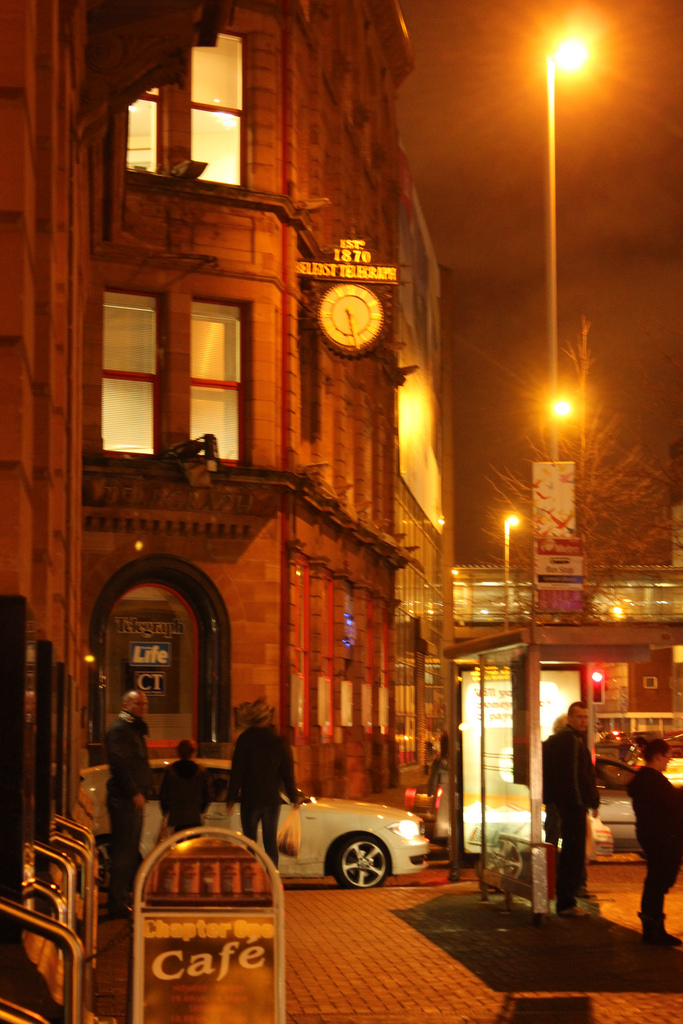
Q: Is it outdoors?
A: Yes, it is outdoors.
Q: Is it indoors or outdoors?
A: It is outdoors.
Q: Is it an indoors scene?
A: No, it is outdoors.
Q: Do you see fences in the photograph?
A: No, there are no fences.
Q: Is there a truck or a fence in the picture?
A: No, there are no fences or trucks.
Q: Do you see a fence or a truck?
A: No, there are no fences or trucks.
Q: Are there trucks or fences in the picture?
A: No, there are no fences or trucks.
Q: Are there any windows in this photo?
A: Yes, there is a window.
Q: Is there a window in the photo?
A: Yes, there is a window.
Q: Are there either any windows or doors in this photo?
A: Yes, there is a window.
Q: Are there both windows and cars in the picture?
A: Yes, there are both a window and a car.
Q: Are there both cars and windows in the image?
A: Yes, there are both a window and a car.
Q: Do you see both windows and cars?
A: Yes, there are both a window and a car.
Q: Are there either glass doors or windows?
A: Yes, there is a glass window.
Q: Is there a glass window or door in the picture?
A: Yes, there is a glass window.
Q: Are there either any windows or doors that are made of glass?
A: Yes, the window is made of glass.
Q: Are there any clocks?
A: Yes, there is a clock.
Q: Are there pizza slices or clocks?
A: Yes, there is a clock.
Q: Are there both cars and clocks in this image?
A: Yes, there are both a clock and a car.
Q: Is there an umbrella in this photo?
A: No, there are no umbrellas.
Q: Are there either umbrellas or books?
A: No, there are no umbrellas or books.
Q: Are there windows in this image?
A: Yes, there is a window.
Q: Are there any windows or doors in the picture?
A: Yes, there is a window.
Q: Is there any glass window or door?
A: Yes, there is a glass window.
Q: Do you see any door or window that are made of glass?
A: Yes, the window is made of glass.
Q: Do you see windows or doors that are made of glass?
A: Yes, the window is made of glass.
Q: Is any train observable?
A: No, there are no trains.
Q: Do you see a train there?
A: No, there are no trains.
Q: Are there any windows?
A: Yes, there is a window.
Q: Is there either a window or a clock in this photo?
A: Yes, there is a window.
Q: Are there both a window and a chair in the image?
A: No, there is a window but no chairs.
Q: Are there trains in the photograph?
A: No, there are no trains.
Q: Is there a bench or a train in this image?
A: No, there are no trains or benches.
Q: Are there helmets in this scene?
A: No, there are no helmets.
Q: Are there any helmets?
A: No, there are no helmets.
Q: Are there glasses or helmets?
A: No, there are no helmets or glasses.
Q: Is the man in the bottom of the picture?
A: Yes, the man is in the bottom of the image.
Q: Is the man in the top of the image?
A: No, the man is in the bottom of the image.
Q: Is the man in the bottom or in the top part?
A: The man is in the bottom of the image.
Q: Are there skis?
A: No, there are no skis.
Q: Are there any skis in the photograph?
A: No, there are no skis.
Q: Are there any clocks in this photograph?
A: Yes, there is a clock.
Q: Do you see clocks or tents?
A: Yes, there is a clock.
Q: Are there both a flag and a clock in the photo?
A: No, there is a clock but no flags.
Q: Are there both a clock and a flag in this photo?
A: No, there is a clock but no flags.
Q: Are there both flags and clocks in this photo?
A: No, there is a clock but no flags.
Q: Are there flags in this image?
A: No, there are no flags.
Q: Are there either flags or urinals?
A: No, there are no flags or urinals.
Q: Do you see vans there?
A: No, there are no vans.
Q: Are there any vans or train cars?
A: No, there are no vans or train cars.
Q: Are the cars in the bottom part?
A: Yes, the cars are in the bottom of the image.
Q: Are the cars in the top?
A: No, the cars are in the bottom of the image.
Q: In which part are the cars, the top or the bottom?
A: The cars are in the bottom of the image.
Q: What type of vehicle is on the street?
A: The vehicles are cars.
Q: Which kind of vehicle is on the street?
A: The vehicles are cars.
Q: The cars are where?
A: The cars are on the street.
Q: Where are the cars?
A: The cars are on the street.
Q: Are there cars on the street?
A: Yes, there are cars on the street.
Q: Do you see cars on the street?
A: Yes, there are cars on the street.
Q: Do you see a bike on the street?
A: No, there are cars on the street.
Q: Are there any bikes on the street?
A: No, there are cars on the street.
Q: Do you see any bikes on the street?
A: No, there are cars on the street.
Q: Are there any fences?
A: No, there are no fences.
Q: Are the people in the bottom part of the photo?
A: Yes, the people are in the bottom of the image.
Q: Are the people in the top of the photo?
A: No, the people are in the bottom of the image.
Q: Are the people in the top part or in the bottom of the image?
A: The people are in the bottom of the image.